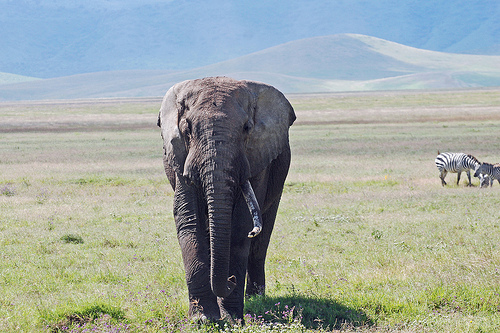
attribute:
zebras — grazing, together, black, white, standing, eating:
[433, 151, 489, 187]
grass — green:
[41, 300, 129, 329]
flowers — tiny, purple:
[272, 301, 281, 315]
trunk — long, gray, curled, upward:
[200, 174, 240, 300]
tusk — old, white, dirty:
[239, 177, 264, 239]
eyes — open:
[240, 120, 250, 133]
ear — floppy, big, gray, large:
[245, 76, 297, 175]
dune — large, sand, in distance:
[2, 34, 499, 99]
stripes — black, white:
[437, 152, 448, 169]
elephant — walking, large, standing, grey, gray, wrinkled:
[158, 71, 296, 332]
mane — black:
[467, 152, 485, 166]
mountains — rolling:
[3, 0, 499, 80]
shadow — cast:
[243, 294, 378, 329]